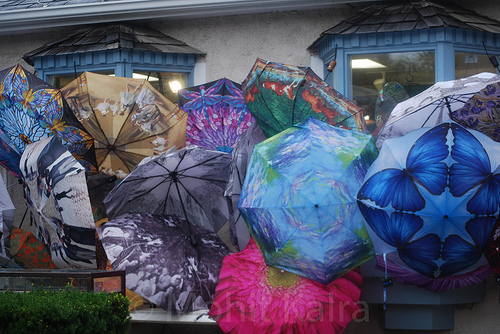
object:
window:
[348, 37, 423, 97]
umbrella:
[357, 120, 499, 281]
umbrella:
[1, 64, 98, 178]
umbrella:
[89, 142, 239, 224]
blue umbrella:
[349, 122, 499, 274]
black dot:
[438, 204, 453, 224]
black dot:
[307, 197, 324, 214]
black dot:
[437, 91, 451, 103]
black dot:
[101, 138, 119, 155]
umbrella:
[58, 68, 189, 179]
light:
[341, 52, 390, 73]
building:
[0, 0, 500, 334]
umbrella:
[239, 43, 373, 141]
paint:
[32, 57, 197, 90]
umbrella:
[204, 240, 365, 333]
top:
[21, 22, 206, 72]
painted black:
[52, 29, 146, 51]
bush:
[1, 287, 133, 332]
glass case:
[0, 259, 134, 297]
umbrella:
[237, 114, 380, 285]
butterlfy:
[447, 122, 499, 217]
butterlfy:
[437, 214, 499, 279]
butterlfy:
[354, 198, 444, 278]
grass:
[8, 278, 128, 330]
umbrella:
[95, 208, 237, 316]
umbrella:
[17, 134, 101, 273]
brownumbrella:
[62, 67, 188, 184]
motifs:
[354, 121, 499, 279]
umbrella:
[176, 75, 258, 160]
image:
[112, 230, 177, 296]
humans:
[87, 81, 163, 130]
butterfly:
[356, 121, 455, 212]